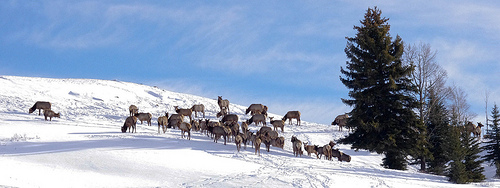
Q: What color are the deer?
A: Brown.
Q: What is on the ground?
A: Snow.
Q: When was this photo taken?
A: During the winter months.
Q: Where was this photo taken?
A: Outside, during the daytime.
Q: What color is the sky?
A: Blue.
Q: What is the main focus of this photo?
A: Animals.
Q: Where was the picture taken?
A: On a hill.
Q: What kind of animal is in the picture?
A: Deer.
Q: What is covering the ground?
A: Snow.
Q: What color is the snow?
A: White.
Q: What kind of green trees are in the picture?
A: Pine trees.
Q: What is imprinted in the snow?
A: Tracks.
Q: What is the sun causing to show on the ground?
A: Shadows.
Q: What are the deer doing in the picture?
A: Grazing.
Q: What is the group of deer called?
A: A herd.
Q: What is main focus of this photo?
A: Wild animals.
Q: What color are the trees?
A: Green.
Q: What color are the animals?
A: Brown.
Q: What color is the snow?
A: White.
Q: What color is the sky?
A: Blue.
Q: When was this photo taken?
A: During the winter months.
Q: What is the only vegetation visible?
A: Trees.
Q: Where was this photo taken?
A: Outside, during the daytime.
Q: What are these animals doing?
A: Grazing for food.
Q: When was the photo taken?
A: Daytime.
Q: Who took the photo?
A: A photographer.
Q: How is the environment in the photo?
A: Cold and snowy.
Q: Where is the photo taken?
A: In the cold regions.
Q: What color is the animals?
A: Brown.